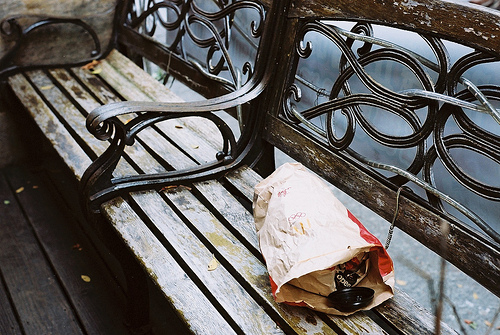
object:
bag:
[248, 160, 399, 321]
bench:
[83, 0, 500, 335]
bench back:
[264, 0, 500, 298]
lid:
[326, 286, 376, 313]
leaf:
[78, 272, 94, 282]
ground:
[3, 159, 194, 335]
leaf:
[12, 186, 30, 195]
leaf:
[79, 58, 107, 76]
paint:
[185, 200, 234, 243]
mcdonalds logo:
[346, 209, 396, 276]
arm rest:
[86, 101, 263, 208]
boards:
[0, 171, 86, 334]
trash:
[286, 251, 379, 312]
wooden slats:
[100, 195, 243, 335]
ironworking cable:
[325, 25, 442, 74]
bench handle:
[79, 94, 262, 142]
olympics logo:
[285, 211, 315, 235]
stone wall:
[148, 1, 490, 183]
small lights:
[159, 73, 173, 85]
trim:
[269, 274, 279, 304]